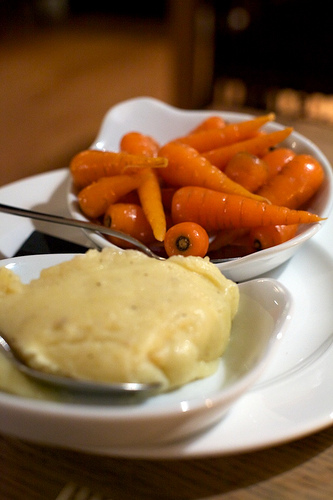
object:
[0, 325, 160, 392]
spoon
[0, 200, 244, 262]
spoon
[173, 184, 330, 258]
carrots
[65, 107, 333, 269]
dish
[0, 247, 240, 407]
food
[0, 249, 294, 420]
dish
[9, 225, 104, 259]
napkin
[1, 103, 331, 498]
table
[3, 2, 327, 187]
background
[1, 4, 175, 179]
floor